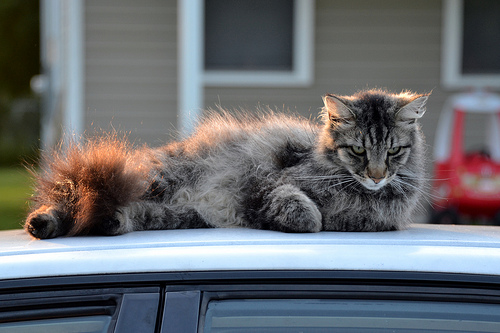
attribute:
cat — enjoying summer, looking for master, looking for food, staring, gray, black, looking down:
[46, 109, 452, 239]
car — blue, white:
[414, 247, 479, 280]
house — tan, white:
[336, 11, 390, 31]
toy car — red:
[431, 90, 499, 198]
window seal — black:
[201, 275, 315, 291]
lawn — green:
[7, 166, 29, 208]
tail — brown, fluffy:
[55, 143, 129, 198]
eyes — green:
[349, 136, 408, 155]